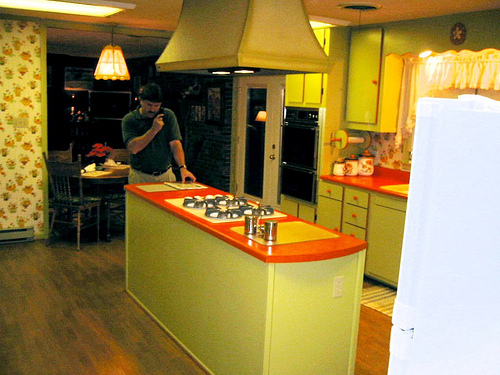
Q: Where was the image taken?
A: It was taken at the kitchen.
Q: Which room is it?
A: It is a kitchen.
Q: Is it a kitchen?
A: Yes, it is a kitchen.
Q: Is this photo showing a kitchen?
A: Yes, it is showing a kitchen.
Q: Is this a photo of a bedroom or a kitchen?
A: It is showing a kitchen.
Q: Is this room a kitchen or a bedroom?
A: It is a kitchen.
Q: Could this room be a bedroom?
A: No, it is a kitchen.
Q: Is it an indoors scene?
A: Yes, it is indoors.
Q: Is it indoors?
A: Yes, it is indoors.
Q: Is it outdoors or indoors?
A: It is indoors.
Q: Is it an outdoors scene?
A: No, it is indoors.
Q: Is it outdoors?
A: No, it is indoors.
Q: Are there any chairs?
A: Yes, there is a chair.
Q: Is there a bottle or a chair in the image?
A: Yes, there is a chair.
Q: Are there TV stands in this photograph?
A: No, there are no TV stands.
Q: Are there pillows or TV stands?
A: No, there are no TV stands or pillows.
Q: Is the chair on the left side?
A: Yes, the chair is on the left of the image.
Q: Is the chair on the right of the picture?
A: No, the chair is on the left of the image.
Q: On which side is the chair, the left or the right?
A: The chair is on the left of the image.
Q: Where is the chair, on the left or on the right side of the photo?
A: The chair is on the left of the image.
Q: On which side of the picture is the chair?
A: The chair is on the left of the image.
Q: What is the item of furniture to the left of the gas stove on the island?
A: The piece of furniture is a chair.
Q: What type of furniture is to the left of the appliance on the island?
A: The piece of furniture is a chair.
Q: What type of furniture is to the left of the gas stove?
A: The piece of furniture is a chair.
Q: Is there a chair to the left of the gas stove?
A: Yes, there is a chair to the left of the gas stove.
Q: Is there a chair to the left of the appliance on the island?
A: Yes, there is a chair to the left of the gas stove.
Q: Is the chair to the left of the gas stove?
A: Yes, the chair is to the left of the gas stove.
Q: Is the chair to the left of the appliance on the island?
A: Yes, the chair is to the left of the gas stove.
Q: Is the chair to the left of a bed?
A: No, the chair is to the left of the gas stove.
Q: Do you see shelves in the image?
A: No, there are no shelves.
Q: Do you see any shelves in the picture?
A: No, there are no shelves.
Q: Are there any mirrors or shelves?
A: No, there are no shelves or mirrors.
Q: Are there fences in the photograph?
A: No, there are no fences.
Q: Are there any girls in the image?
A: No, there are no girls.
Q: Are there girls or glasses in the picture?
A: No, there are no girls or glasses.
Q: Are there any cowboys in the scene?
A: No, there are no cowboys.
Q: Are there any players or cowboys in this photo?
A: No, there are no cowboys or players.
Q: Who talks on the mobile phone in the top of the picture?
A: The man talks on the mobile phone.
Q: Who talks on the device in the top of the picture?
A: The man talks on the mobile phone.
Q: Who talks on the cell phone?
A: The man talks on the mobile phone.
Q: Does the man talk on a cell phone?
A: Yes, the man talks on a cell phone.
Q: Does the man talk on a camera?
A: No, the man talks on a cell phone.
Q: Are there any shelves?
A: No, there are no shelves.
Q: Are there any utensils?
A: No, there are no utensils.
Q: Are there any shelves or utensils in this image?
A: No, there are no utensils or shelves.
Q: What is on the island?
A: The gas stove is on the island.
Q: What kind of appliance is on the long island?
A: The appliance is a gas stove.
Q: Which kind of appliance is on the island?
A: The appliance is a gas stove.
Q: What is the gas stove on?
A: The gas stove is on the island.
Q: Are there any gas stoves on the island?
A: Yes, there is a gas stove on the island.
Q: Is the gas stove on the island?
A: Yes, the gas stove is on the island.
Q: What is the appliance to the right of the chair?
A: The appliance is a gas stove.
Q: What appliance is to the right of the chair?
A: The appliance is a gas stove.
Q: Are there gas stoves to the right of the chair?
A: Yes, there is a gas stove to the right of the chair.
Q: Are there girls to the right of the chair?
A: No, there is a gas stove to the right of the chair.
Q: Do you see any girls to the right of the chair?
A: No, there is a gas stove to the right of the chair.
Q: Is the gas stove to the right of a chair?
A: Yes, the gas stove is to the right of a chair.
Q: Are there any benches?
A: No, there are no benches.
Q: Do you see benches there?
A: No, there are no benches.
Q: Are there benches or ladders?
A: No, there are no benches or ladders.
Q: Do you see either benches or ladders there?
A: No, there are no benches or ladders.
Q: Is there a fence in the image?
A: No, there are no fences.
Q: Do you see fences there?
A: No, there are no fences.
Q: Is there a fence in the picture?
A: No, there are no fences.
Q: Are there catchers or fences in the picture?
A: No, there are no fences or catchers.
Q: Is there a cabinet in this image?
A: Yes, there is a cabinet.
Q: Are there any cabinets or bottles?
A: Yes, there is a cabinet.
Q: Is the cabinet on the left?
A: No, the cabinet is on the right of the image.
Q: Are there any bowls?
A: No, there are no bowls.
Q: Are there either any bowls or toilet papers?
A: No, there are no bowls or toilet papers.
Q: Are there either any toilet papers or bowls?
A: No, there are no bowls or toilet papers.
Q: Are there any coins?
A: No, there are no coins.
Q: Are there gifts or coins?
A: No, there are no coins or gifts.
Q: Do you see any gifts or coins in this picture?
A: No, there are no coins or gifts.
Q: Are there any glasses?
A: No, there are no glasses.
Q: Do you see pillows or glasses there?
A: No, there are no glasses or pillows.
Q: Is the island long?
A: Yes, the island is long.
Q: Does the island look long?
A: Yes, the island is long.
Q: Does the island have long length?
A: Yes, the island is long.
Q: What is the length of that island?
A: The island is long.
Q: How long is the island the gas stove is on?
A: The island is long.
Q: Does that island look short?
A: No, the island is long.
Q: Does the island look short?
A: No, the island is long.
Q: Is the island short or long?
A: The island is long.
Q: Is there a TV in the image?
A: No, there are no televisions.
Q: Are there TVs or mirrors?
A: No, there are no TVs or mirrors.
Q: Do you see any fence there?
A: No, there are no fences.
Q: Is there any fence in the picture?
A: No, there are no fences.